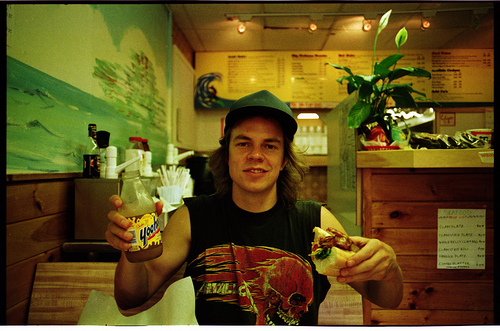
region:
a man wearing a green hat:
[205, 84, 312, 229]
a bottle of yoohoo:
[107, 165, 172, 270]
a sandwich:
[295, 205, 393, 290]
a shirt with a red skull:
[163, 65, 351, 329]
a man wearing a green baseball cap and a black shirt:
[143, 80, 364, 327]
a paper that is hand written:
[423, 190, 494, 284]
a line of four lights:
[225, 4, 465, 53]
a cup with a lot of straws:
[151, 157, 196, 208]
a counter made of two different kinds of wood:
[348, 135, 498, 317]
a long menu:
[198, 39, 499, 103]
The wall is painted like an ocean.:
[27, 28, 176, 185]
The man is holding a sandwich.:
[304, 208, 381, 283]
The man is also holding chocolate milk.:
[96, 143, 189, 283]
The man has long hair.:
[210, 89, 305, 206]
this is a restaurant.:
[47, 24, 468, 306]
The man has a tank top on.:
[190, 192, 340, 327]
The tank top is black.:
[168, 178, 355, 330]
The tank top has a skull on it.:
[196, 230, 353, 320]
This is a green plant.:
[336, 42, 443, 154]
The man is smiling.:
[206, 80, 309, 217]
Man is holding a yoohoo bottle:
[77, 166, 203, 299]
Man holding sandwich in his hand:
[300, 203, 428, 327]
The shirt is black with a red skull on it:
[185, 172, 323, 329]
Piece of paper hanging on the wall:
[416, 203, 496, 291]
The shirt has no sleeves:
[157, 172, 295, 324]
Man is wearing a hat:
[232, 90, 304, 158]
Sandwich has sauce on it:
[312, 217, 362, 281]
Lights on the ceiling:
[207, 14, 442, 51]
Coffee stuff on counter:
[69, 112, 173, 182]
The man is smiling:
[205, 108, 313, 213]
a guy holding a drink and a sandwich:
[90, 55, 416, 329]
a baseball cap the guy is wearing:
[222, 85, 300, 135]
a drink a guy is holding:
[109, 164, 168, 265]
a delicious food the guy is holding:
[307, 217, 361, 284]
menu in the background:
[215, 48, 323, 88]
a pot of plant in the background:
[343, 58, 400, 143]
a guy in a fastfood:
[104, 86, 411, 326]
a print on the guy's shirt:
[197, 242, 307, 328]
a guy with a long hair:
[196, 78, 313, 221]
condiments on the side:
[76, 120, 181, 176]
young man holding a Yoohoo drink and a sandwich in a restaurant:
[101, 86, 403, 326]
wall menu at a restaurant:
[194, 48, 496, 105]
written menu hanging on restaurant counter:
[436, 208, 486, 270]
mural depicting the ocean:
[5, 0, 170, 175]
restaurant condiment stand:
[63, 120, 194, 256]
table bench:
[26, 260, 363, 325]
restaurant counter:
[353, 149, 498, 324]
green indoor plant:
[323, 5, 433, 160]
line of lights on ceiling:
[220, 10, 445, 35]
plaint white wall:
[171, 44, 193, 151]